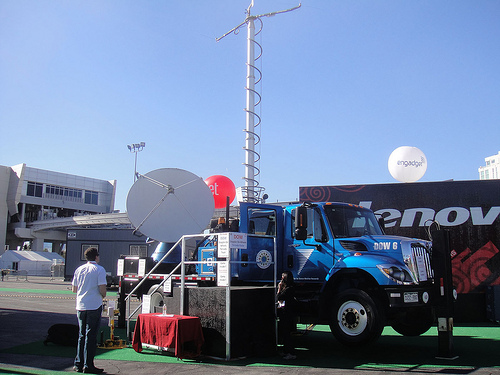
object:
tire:
[328, 289, 385, 346]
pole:
[134, 153, 138, 172]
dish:
[125, 168, 215, 243]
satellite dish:
[132, 169, 204, 237]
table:
[132, 312, 204, 361]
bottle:
[162, 304, 167, 317]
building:
[0, 163, 117, 252]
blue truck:
[118, 203, 437, 347]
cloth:
[132, 313, 204, 359]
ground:
[362, 170, 402, 222]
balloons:
[387, 144, 427, 183]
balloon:
[203, 174, 235, 210]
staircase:
[121, 230, 279, 364]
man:
[67, 245, 109, 374]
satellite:
[120, 140, 218, 259]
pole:
[243, 0, 262, 199]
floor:
[212, 213, 297, 255]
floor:
[127, 169, 282, 213]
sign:
[296, 182, 500, 328]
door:
[240, 202, 286, 280]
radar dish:
[125, 166, 217, 246]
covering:
[131, 313, 205, 358]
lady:
[53, 246, 119, 373]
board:
[298, 177, 500, 328]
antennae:
[215, 0, 300, 205]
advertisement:
[299, 179, 499, 324]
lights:
[125, 140, 146, 181]